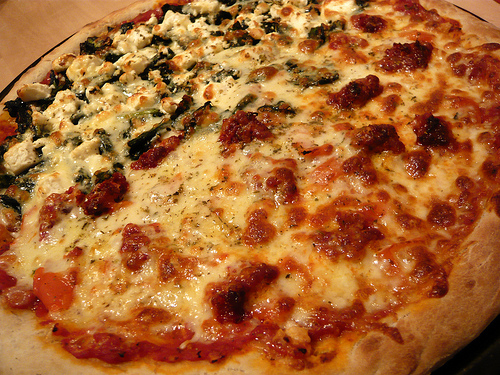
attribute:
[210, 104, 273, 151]
meat — large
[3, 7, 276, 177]
cheesy pizza — chessy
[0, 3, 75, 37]
table — brown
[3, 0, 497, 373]
pizza — Half, large